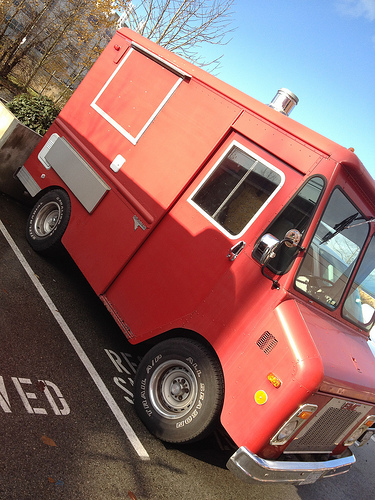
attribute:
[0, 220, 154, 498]
parking space — reserved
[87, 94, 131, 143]
trim — white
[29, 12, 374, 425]
truck — old,  front 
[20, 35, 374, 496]
parked truck — red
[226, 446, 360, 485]
bumper — chrome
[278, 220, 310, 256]
mirror — side 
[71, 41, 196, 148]
opening — square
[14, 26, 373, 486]
truck —  top, red, slanted, large red , side 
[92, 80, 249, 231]
van — parked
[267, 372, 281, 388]
signal light — orange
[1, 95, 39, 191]
planter — concrete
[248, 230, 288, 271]
mirror — side view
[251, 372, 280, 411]
lights — side safety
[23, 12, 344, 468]
van — red, orange